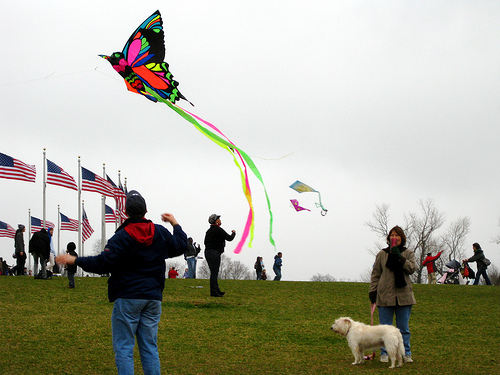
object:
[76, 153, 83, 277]
pole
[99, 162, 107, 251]
pole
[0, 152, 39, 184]
flag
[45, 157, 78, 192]
flag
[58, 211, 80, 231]
flag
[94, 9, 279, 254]
skies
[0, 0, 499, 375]
scene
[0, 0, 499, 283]
sky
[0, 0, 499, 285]
clouds